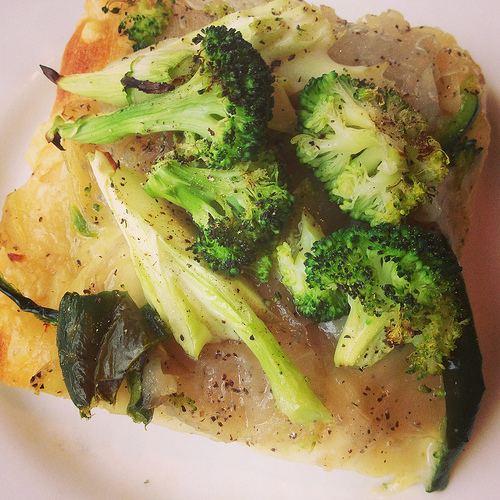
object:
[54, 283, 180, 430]
vegetable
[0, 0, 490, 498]
food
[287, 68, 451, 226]
vegetables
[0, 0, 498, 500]
plate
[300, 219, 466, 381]
broccolo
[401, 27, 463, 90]
meat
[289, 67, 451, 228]
broccoli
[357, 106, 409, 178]
broccoli floret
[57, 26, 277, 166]
broccoli spear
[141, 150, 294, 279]
broccoli spear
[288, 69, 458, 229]
broccoli spear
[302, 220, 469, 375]
broccoli spear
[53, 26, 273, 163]
vegetable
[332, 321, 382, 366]
broccoli stalk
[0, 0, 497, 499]
background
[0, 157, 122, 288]
cheese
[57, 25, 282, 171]
floret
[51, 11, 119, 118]
bread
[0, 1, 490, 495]
toast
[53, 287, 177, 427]
spinach